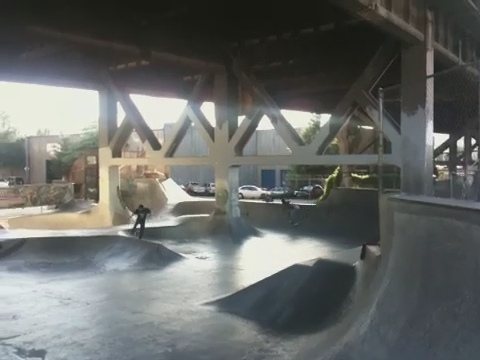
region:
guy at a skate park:
[70, 107, 139, 275]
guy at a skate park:
[20, 32, 237, 270]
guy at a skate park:
[223, 71, 340, 344]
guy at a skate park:
[78, 82, 194, 299]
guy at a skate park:
[61, 173, 381, 242]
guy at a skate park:
[4, 119, 350, 275]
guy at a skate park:
[83, 270, 183, 338]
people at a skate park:
[88, 168, 352, 257]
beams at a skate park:
[105, 76, 406, 153]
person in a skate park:
[124, 200, 165, 244]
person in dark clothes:
[124, 206, 163, 243]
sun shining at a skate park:
[3, 88, 205, 262]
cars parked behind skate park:
[190, 177, 338, 196]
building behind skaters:
[24, 131, 116, 187]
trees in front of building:
[51, 127, 105, 168]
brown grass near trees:
[17, 212, 114, 234]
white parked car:
[239, 181, 271, 200]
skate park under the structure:
[36, 197, 435, 354]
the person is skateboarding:
[121, 203, 150, 233]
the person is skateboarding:
[280, 194, 310, 234]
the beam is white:
[405, 50, 439, 196]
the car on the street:
[237, 181, 269, 202]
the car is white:
[231, 181, 271, 202]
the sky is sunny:
[3, 86, 94, 128]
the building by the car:
[169, 127, 340, 186]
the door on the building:
[259, 168, 273, 188]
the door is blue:
[261, 166, 273, 185]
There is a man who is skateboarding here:
[129, 182, 166, 275]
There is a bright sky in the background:
[38, 86, 47, 106]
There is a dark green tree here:
[3, 121, 11, 158]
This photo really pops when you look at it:
[101, 112, 174, 356]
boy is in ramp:
[105, 187, 155, 243]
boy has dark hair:
[126, 201, 146, 212]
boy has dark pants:
[120, 211, 154, 224]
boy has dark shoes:
[120, 210, 150, 242]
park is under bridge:
[153, 136, 450, 304]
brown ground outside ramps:
[20, 211, 78, 227]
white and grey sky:
[30, 96, 78, 124]